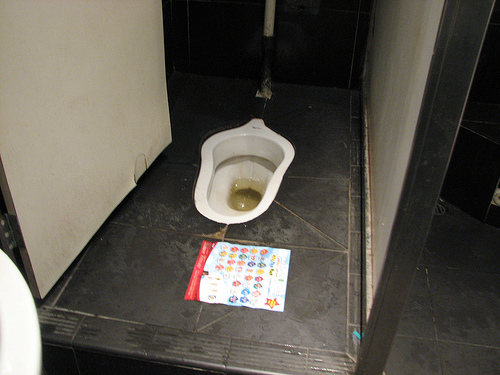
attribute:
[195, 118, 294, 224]
toilet — dirty, soiled, white, old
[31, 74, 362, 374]
floor — black, blue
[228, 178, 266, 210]
water — brown, yellow, filthy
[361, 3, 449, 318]
wall — white, sheetrock, divided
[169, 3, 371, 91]
wall — black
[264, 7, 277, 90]
pipe — black, connected, exposed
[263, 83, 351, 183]
tile — black, dirty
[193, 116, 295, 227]
urinal — dirty, white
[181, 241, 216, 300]
page — red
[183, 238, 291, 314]
sticker — reward, white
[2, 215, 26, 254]
hinges — black